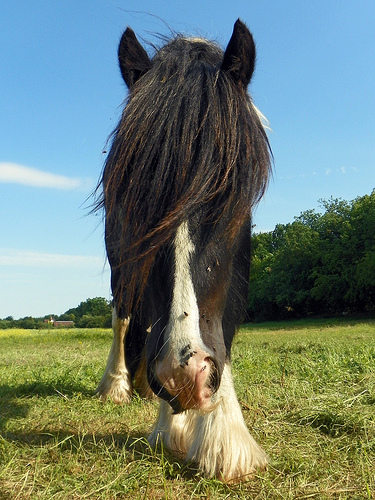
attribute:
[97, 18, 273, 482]
horse — close, grazing, eating, standing, owned, hungry, clydesdale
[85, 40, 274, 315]
mane — long, brown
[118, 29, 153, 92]
ear — brown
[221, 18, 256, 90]
ear — brown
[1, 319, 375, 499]
field — grassy, green, unkempt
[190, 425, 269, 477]
hoof — hairy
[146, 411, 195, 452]
hoof — hairy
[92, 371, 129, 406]
hoof — hairy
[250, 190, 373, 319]
trees — green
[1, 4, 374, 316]
sky — blue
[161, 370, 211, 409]
nose — pink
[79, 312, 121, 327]
trees — green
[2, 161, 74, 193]
cloud — white